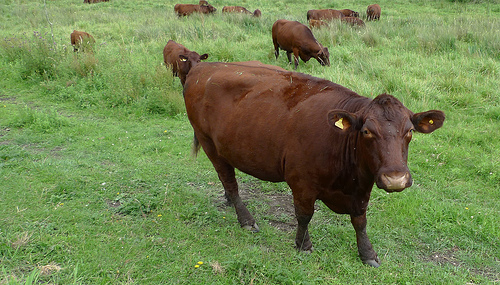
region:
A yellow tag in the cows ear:
[328, 114, 342, 131]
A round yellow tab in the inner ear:
[426, 119, 434, 125]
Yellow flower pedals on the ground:
[191, 255, 205, 271]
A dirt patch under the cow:
[251, 186, 285, 248]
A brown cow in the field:
[186, 62, 451, 278]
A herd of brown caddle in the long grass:
[145, 3, 395, 62]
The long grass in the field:
[407, 8, 498, 100]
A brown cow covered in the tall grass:
[61, 21, 101, 57]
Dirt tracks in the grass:
[0, 86, 89, 197]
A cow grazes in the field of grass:
[268, 13, 333, 73]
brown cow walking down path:
[185, 58, 442, 279]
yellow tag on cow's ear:
[331, 115, 348, 130]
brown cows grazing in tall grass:
[63, 3, 398, 88]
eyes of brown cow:
[357, 125, 414, 147]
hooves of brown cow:
[219, 185, 379, 275]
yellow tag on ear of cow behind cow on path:
[176, 52, 186, 66]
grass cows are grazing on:
[12, 4, 497, 116]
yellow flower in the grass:
[192, 258, 204, 269]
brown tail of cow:
[186, 131, 208, 157]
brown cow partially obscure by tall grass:
[59, 26, 96, 56]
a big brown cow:
[171, 52, 447, 272]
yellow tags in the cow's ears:
[328, 105, 441, 138]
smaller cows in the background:
[62, 0, 385, 83]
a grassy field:
[2, 1, 498, 283]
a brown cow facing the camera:
[173, 55, 446, 269]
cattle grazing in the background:
[68, 0, 389, 85]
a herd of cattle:
[67, 1, 448, 268]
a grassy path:
[4, 51, 497, 281]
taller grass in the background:
[1, 0, 497, 176]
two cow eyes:
[353, 123, 418, 148]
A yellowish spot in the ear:
[336, 120, 342, 126]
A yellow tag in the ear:
[425, 120, 430, 125]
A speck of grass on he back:
[286, 72, 291, 78]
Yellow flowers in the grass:
[193, 258, 203, 270]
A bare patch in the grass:
[276, 195, 291, 208]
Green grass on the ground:
[455, 96, 494, 159]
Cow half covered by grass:
[70, 28, 95, 49]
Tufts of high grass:
[423, 20, 448, 44]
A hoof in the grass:
[243, 225, 260, 234]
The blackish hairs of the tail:
[192, 136, 198, 155]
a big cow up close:
[146, 41, 473, 273]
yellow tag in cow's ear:
[332, 117, 348, 132]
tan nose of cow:
[386, 171, 416, 193]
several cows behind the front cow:
[88, 2, 410, 84]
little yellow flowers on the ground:
[185, 250, 212, 275]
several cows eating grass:
[116, 3, 425, 70]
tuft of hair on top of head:
[372, 89, 407, 126]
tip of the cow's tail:
[188, 132, 202, 162]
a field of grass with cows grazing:
[8, 7, 498, 267]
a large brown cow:
[163, 38, 465, 272]